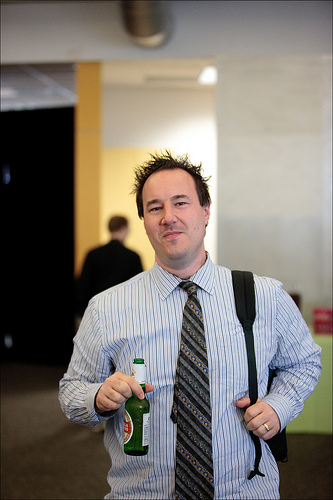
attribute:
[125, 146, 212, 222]
hair — spiked, spiky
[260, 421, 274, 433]
wedding band — gold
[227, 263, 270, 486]
strap — black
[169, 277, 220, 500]
tie — ornate, black, dark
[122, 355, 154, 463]
bottle — glass, beer, green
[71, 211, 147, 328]
man — blurry, smiling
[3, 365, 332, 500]
carpet — brown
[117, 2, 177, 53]
tube — metal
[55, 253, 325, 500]
shirt — striped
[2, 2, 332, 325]
wall — white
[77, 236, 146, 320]
shirt — black